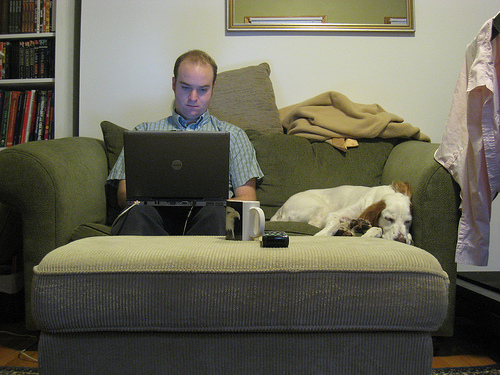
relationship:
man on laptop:
[81, 33, 297, 242] [105, 121, 268, 216]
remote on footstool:
[255, 210, 297, 259] [34, 208, 452, 345]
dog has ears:
[262, 166, 442, 252] [351, 199, 402, 229]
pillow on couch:
[231, 59, 286, 131] [37, 109, 452, 285]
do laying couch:
[262, 166, 442, 252] [37, 109, 452, 285]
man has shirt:
[81, 33, 297, 242] [236, 124, 267, 173]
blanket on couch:
[286, 75, 404, 164] [37, 109, 452, 285]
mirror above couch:
[218, 14, 428, 45] [37, 109, 452, 285]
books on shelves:
[7, 33, 60, 79] [15, 9, 101, 163]